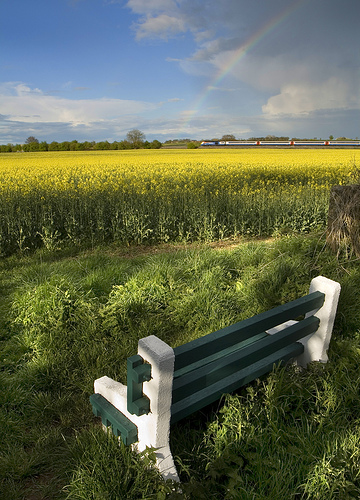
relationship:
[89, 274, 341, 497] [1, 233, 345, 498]
bench in grass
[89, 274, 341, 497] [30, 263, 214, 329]
bench in grass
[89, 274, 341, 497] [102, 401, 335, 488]
bench in grass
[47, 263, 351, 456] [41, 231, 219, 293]
bench in grass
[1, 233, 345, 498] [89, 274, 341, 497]
grass near bench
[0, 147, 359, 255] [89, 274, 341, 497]
flowers near bench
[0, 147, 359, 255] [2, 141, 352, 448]
flowers in field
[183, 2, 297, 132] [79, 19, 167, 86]
rainbow in sky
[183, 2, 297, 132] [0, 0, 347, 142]
rainbow across sky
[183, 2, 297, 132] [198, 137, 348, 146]
rainbow over train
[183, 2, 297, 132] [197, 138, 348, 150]
rainbow over train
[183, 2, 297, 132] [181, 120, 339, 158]
rainbow over train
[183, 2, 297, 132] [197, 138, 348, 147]
rainbow over train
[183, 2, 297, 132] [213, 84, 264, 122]
rainbow across sky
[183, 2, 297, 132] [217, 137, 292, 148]
rainbow over train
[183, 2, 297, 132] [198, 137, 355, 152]
rainbow over train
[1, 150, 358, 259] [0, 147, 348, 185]
grass with flowers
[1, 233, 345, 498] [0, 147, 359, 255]
grass with flowers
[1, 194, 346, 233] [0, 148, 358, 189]
grass with flowers